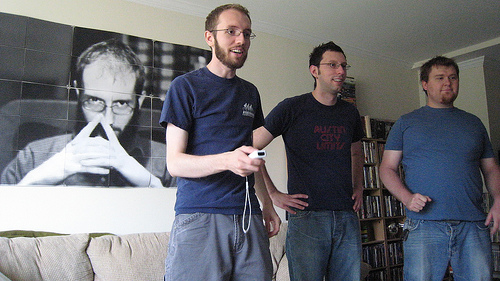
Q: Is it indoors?
A: Yes, it is indoors.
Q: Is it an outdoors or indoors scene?
A: It is indoors.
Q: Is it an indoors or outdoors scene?
A: It is indoors.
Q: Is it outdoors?
A: No, it is indoors.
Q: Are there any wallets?
A: No, there are no wallets.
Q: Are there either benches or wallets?
A: No, there are no wallets or benches.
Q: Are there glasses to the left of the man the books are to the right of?
A: Yes, there are glasses to the left of the man.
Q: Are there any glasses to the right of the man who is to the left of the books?
A: No, the glasses are to the left of the man.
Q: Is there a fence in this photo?
A: No, there are no fences.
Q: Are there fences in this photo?
A: No, there are no fences.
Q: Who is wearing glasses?
A: The man is wearing glasses.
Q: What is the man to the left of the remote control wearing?
A: The man is wearing glasses.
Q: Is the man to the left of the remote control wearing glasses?
A: Yes, the man is wearing glasses.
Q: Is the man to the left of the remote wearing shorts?
A: No, the man is wearing glasses.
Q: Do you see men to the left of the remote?
A: Yes, there is a man to the left of the remote.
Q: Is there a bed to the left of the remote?
A: No, there is a man to the left of the remote.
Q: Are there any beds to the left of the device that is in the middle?
A: No, there is a man to the left of the remote.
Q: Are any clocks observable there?
A: No, there are no clocks.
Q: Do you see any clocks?
A: No, there are no clocks.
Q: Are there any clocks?
A: No, there are no clocks.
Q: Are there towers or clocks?
A: No, there are no clocks or towers.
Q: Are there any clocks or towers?
A: No, there are no clocks or towers.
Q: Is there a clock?
A: No, there are no clocks.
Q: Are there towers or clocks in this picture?
A: No, there are no clocks or towers.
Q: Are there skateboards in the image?
A: No, there are no skateboards.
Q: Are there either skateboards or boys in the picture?
A: No, there are no skateboards or boys.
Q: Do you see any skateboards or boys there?
A: No, there are no skateboards or boys.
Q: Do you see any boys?
A: No, there are no boys.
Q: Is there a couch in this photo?
A: Yes, there is a couch.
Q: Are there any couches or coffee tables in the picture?
A: Yes, there is a couch.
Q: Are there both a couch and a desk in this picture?
A: No, there is a couch but no desks.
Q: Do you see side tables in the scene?
A: No, there are no side tables.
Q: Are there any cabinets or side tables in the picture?
A: No, there are no side tables or cabinets.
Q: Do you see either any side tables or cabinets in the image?
A: No, there are no side tables or cabinets.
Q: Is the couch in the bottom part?
A: Yes, the couch is in the bottom of the image.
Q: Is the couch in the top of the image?
A: No, the couch is in the bottom of the image.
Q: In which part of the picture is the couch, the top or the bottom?
A: The couch is in the bottom of the image.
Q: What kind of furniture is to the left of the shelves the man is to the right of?
A: The piece of furniture is a couch.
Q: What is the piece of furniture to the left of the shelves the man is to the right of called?
A: The piece of furniture is a couch.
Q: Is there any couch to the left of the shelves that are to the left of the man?
A: Yes, there is a couch to the left of the shelves.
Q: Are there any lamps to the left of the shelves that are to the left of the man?
A: No, there is a couch to the left of the shelves.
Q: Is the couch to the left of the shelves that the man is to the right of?
A: Yes, the couch is to the left of the shelves.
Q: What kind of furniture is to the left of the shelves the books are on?
A: The piece of furniture is a couch.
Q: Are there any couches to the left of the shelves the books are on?
A: Yes, there is a couch to the left of the shelves.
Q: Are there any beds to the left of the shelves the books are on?
A: No, there is a couch to the left of the shelves.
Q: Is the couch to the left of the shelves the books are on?
A: Yes, the couch is to the left of the shelves.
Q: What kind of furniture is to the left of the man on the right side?
A: The piece of furniture is a couch.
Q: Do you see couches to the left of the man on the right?
A: Yes, there is a couch to the left of the man.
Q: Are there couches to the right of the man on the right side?
A: No, the couch is to the left of the man.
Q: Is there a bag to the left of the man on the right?
A: No, there is a couch to the left of the man.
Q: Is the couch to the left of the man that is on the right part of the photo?
A: Yes, the couch is to the left of the man.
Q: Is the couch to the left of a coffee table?
A: No, the couch is to the left of the man.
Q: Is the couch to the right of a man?
A: No, the couch is to the left of a man.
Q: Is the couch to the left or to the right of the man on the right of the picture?
A: The couch is to the left of the man.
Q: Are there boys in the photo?
A: No, there are no boys.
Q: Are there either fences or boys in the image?
A: No, there are no boys or fences.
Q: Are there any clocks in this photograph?
A: No, there are no clocks.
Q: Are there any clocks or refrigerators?
A: No, there are no clocks or refrigerators.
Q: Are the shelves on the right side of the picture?
A: Yes, the shelves are on the right of the image.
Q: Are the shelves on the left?
A: No, the shelves are on the right of the image.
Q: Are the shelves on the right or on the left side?
A: The shelves are on the right of the image.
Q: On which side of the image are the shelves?
A: The shelves are on the right of the image.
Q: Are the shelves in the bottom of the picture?
A: Yes, the shelves are in the bottom of the image.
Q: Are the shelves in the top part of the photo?
A: No, the shelves are in the bottom of the image.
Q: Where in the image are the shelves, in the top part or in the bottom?
A: The shelves are in the bottom of the image.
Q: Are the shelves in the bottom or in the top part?
A: The shelves are in the bottom of the image.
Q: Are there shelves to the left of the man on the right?
A: Yes, there are shelves to the left of the man.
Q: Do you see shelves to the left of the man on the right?
A: Yes, there are shelves to the left of the man.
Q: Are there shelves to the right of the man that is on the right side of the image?
A: No, the shelves are to the left of the man.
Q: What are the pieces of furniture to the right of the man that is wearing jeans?
A: The pieces of furniture are shelves.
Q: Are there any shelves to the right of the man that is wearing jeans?
A: Yes, there are shelves to the right of the man.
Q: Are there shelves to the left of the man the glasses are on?
A: No, the shelves are to the right of the man.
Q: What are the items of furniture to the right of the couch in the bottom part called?
A: The pieces of furniture are shelves.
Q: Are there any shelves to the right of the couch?
A: Yes, there are shelves to the right of the couch.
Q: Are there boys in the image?
A: No, there are no boys.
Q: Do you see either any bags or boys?
A: No, there are no boys or bags.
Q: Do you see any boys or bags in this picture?
A: No, there are no boys or bags.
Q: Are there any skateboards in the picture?
A: No, there are no skateboards.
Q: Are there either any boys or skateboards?
A: No, there are no skateboards or boys.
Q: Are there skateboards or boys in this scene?
A: No, there are no skateboards or boys.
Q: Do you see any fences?
A: No, there are no fences.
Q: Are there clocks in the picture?
A: No, there are no clocks.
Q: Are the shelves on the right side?
A: Yes, the shelves are on the right of the image.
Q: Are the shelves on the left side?
A: No, the shelves are on the right of the image.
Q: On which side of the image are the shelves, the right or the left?
A: The shelves are on the right of the image.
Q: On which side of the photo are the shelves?
A: The shelves are on the right of the image.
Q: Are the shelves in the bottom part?
A: Yes, the shelves are in the bottom of the image.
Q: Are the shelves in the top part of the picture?
A: No, the shelves are in the bottom of the image.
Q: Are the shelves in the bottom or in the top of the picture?
A: The shelves are in the bottom of the image.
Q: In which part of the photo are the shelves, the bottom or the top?
A: The shelves are in the bottom of the image.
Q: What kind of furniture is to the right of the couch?
A: The pieces of furniture are shelves.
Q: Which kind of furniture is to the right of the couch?
A: The pieces of furniture are shelves.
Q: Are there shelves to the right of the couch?
A: Yes, there are shelves to the right of the couch.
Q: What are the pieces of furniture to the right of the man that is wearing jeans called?
A: The pieces of furniture are shelves.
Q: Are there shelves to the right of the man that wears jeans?
A: Yes, there are shelves to the right of the man.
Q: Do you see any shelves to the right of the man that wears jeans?
A: Yes, there are shelves to the right of the man.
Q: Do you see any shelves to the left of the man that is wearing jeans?
A: No, the shelves are to the right of the man.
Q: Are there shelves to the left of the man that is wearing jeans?
A: No, the shelves are to the right of the man.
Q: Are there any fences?
A: No, there are no fences.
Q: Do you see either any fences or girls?
A: No, there are no fences or girls.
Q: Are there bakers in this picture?
A: No, there are no bakers.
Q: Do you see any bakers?
A: No, there are no bakers.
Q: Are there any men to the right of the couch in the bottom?
A: Yes, there is a man to the right of the couch.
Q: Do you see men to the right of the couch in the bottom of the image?
A: Yes, there is a man to the right of the couch.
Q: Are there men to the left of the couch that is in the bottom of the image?
A: No, the man is to the right of the couch.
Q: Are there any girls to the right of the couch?
A: No, there is a man to the right of the couch.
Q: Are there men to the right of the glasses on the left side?
A: Yes, there is a man to the right of the glasses.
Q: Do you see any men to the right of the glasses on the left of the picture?
A: Yes, there is a man to the right of the glasses.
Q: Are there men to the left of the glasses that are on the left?
A: No, the man is to the right of the glasses.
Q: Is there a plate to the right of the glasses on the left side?
A: No, there is a man to the right of the glasses.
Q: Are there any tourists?
A: No, there are no tourists.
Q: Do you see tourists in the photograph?
A: No, there are no tourists.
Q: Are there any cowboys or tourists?
A: No, there are no tourists or cowboys.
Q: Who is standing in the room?
A: The man is standing in the room.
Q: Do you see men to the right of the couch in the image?
A: Yes, there is a man to the right of the couch.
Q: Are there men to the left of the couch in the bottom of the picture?
A: No, the man is to the right of the couch.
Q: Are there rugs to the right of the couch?
A: No, there is a man to the right of the couch.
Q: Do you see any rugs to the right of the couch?
A: No, there is a man to the right of the couch.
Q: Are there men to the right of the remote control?
A: Yes, there is a man to the right of the remote control.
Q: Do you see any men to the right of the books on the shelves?
A: Yes, there is a man to the right of the books.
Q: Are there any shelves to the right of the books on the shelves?
A: No, there is a man to the right of the books.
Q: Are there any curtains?
A: No, there are no curtains.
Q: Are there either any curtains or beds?
A: No, there are no curtains or beds.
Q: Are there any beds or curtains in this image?
A: No, there are no curtains or beds.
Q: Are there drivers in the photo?
A: No, there are no drivers.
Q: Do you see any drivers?
A: No, there are no drivers.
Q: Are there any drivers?
A: No, there are no drivers.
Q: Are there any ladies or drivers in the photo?
A: No, there are no drivers or ladies.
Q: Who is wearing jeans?
A: The man is wearing jeans.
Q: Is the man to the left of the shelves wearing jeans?
A: Yes, the man is wearing jeans.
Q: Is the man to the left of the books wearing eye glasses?
A: No, the man is wearing jeans.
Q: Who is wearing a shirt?
A: The man is wearing a shirt.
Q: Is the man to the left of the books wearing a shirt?
A: Yes, the man is wearing a shirt.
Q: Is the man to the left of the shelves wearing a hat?
A: No, the man is wearing a shirt.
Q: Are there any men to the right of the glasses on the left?
A: Yes, there is a man to the right of the glasses.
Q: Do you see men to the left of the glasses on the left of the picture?
A: No, the man is to the right of the glasses.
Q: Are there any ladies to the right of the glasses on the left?
A: No, there is a man to the right of the glasses.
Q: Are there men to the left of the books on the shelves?
A: Yes, there is a man to the left of the books.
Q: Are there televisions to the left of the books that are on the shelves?
A: No, there is a man to the left of the books.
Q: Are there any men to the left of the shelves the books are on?
A: Yes, there is a man to the left of the shelves.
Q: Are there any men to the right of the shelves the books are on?
A: No, the man is to the left of the shelves.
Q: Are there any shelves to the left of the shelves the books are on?
A: No, there is a man to the left of the shelves.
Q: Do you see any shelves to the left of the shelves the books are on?
A: No, there is a man to the left of the shelves.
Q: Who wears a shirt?
A: The man wears a shirt.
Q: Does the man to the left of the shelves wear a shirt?
A: Yes, the man wears a shirt.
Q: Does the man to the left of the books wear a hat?
A: No, the man wears a shirt.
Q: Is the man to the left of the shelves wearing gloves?
A: No, the man is wearing jeans.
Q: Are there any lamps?
A: No, there are no lamps.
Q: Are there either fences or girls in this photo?
A: No, there are no fences or girls.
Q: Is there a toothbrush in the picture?
A: No, there are no toothbrushes.